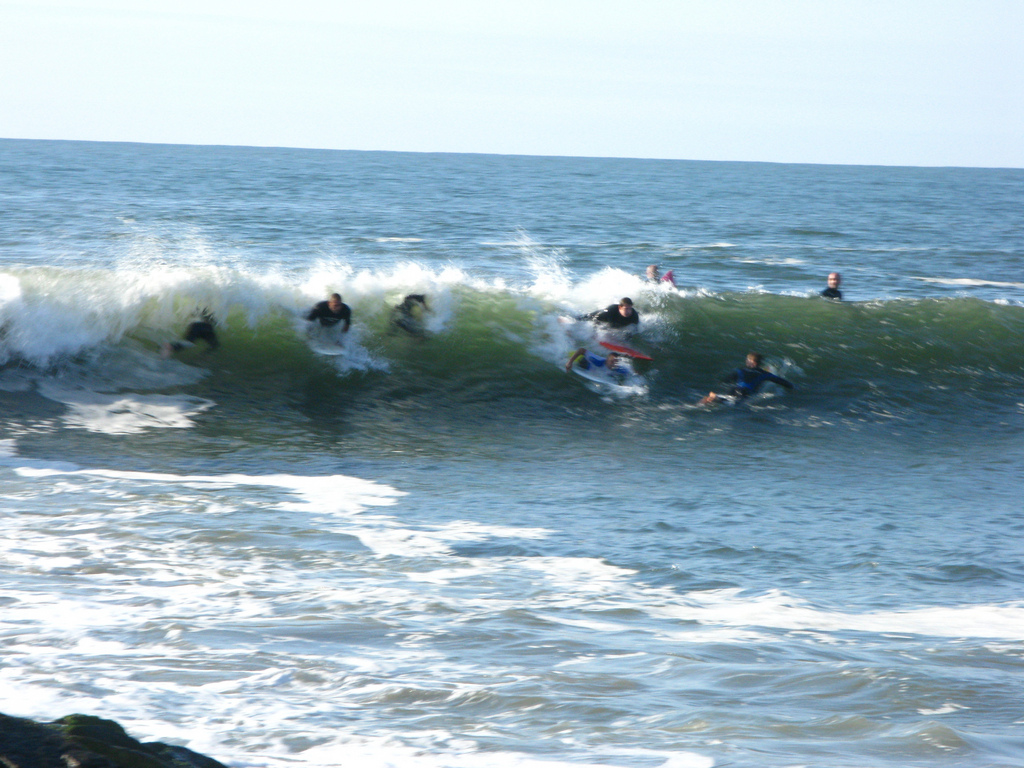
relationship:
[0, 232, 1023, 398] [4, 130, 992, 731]
wave in water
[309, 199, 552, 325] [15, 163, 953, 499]
foams of wave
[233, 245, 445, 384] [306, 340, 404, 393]
man on surfboard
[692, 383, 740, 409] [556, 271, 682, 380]
feet of a person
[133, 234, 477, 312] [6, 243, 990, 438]
splash from wave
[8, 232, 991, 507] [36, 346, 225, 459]
wave with foam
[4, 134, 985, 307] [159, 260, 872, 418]
ocean behind surfers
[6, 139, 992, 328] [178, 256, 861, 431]
water behind surfers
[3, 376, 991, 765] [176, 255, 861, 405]
water in front of surfers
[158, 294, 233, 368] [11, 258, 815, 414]
surfers riding wave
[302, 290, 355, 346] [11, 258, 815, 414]
man riding wave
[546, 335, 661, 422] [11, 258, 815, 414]
surfers riding wave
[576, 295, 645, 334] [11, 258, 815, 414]
people riding wave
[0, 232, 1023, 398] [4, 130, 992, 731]
wave on water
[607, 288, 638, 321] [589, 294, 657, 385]
head of a person